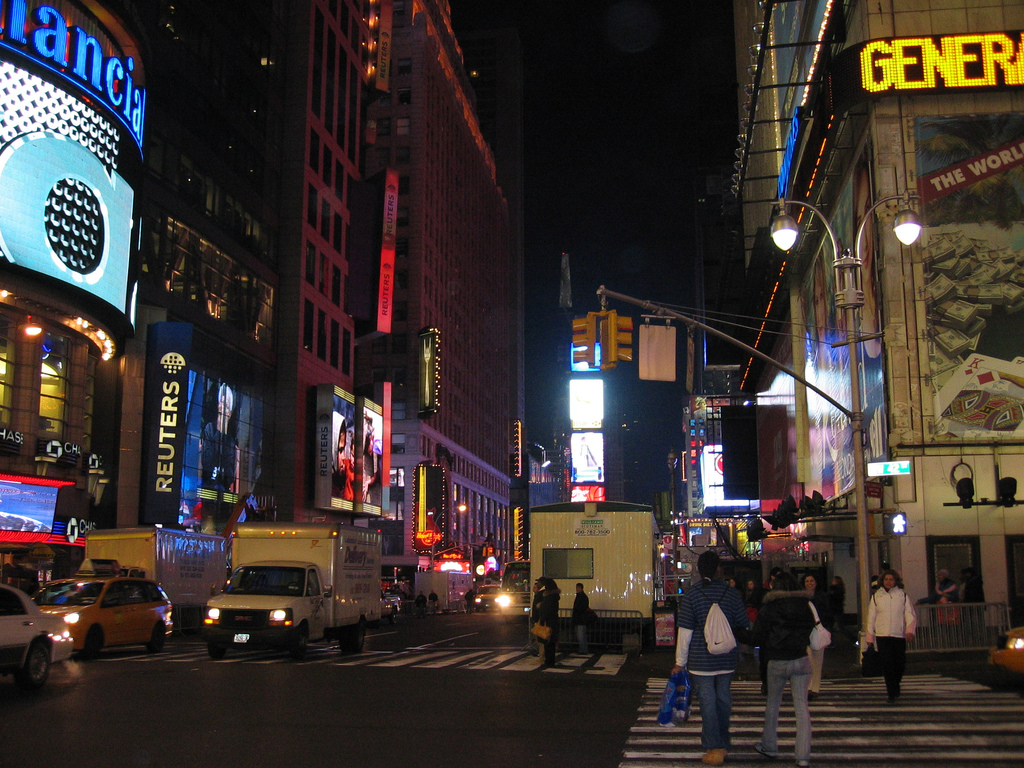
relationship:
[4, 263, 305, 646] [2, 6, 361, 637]
wall on building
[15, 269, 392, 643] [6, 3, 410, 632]
wall on building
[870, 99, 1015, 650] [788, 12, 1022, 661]
wall on building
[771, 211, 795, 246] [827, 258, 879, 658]
light on pole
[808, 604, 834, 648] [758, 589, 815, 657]
bag on shoulder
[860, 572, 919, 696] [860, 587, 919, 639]
person in coat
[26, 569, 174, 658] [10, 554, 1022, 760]
car in street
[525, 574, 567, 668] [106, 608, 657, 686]
person in crosswalk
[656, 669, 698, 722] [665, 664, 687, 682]
bag in hand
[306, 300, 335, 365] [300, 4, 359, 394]
window on building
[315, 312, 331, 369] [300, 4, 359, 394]
window on building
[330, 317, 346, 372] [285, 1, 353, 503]
window on building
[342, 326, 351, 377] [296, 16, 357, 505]
window on building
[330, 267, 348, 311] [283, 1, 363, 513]
window on building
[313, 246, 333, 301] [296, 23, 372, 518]
window on building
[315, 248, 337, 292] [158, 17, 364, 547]
window on building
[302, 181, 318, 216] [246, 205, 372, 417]
window on building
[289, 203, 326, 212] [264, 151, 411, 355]
window on building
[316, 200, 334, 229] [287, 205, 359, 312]
window on building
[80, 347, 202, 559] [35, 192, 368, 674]
wall on side of building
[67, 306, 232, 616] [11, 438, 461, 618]
wall on side of building